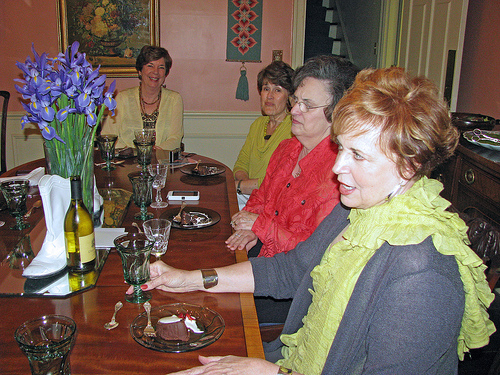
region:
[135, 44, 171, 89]
the woman is smiling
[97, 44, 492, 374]
four women are sitting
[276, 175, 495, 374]
the scarf is green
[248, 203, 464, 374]
the shirt is gray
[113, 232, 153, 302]
the cup is empty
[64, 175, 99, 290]
a bottle of wine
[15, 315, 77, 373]
an empty glass cup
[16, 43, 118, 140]
the flowers are purple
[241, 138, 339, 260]
the shirt is red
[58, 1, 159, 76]
painting on the wall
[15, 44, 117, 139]
purple lilies in bloom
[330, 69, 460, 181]
strawberry blonde hair on a woman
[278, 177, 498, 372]
a frilly green scarf on a woman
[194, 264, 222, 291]
a cuff bracelet on a woman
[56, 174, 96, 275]
a green wine bottle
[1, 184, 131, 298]
a mirrored centerpiece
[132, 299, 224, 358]
a plate with a piece of cake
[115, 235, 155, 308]
a green wine glass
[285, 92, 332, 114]
glasses on a woman's face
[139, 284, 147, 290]
red nail polish on a woman's thumb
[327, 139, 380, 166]
the eyes of a woman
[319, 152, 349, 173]
the nose of a woman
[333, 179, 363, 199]
the mouth of a woman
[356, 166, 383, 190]
the cheek of a woman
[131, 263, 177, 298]
the hand of a woman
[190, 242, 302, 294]
the arm of a woman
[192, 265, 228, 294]
the bracelet of a woman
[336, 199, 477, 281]
the scarf of a woman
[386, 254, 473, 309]
the shoulder of a woman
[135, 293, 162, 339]
siver fork lying on plate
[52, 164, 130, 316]
greenish bottle of wine in middle of table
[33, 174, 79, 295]
white boot in middle of table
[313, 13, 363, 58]
staircase leading upstairs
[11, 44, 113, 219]
tall purple flowered centerpiece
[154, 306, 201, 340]
chocolate desert with red cherry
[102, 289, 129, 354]
silver spoon lying on brown table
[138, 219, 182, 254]
empty clear drinking glass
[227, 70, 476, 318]
a bunch of elderly women at a table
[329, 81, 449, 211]
the head of a woman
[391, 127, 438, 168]
the hair of a woman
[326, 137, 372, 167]
the eyes of a woman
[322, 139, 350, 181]
the nose of a woman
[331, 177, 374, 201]
the mouth of a woman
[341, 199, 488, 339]
the scarf of a woman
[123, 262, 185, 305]
the hand of a woman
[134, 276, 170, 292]
the thumb of a woman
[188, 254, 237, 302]
the bracelet of a woman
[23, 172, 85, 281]
white boot on the table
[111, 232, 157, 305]
glass is green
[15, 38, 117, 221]
flowers are purplish and yellow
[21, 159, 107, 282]
boot on sides of flowers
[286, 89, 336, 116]
woman is wearing glasses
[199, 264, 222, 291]
woman is wearing a bracelet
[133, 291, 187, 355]
fork is on the plate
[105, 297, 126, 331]
spoon next to plate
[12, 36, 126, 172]
The purple flowers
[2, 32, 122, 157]
A set of purple flowers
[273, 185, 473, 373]
The green scarf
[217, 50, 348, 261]
The woman wearing red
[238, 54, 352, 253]
A woman wearing red